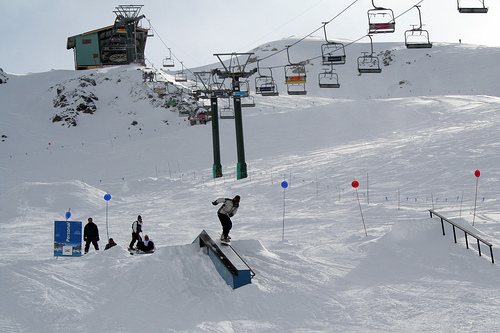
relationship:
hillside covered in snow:
[2, 32, 495, 329] [0, 34, 499, 331]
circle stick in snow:
[350, 181, 369, 238] [0, 34, 499, 331]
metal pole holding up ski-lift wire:
[228, 94, 249, 181] [252, 2, 359, 64]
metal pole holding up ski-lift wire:
[207, 97, 224, 179] [261, 2, 423, 73]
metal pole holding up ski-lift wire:
[207, 97, 224, 179] [140, 11, 195, 79]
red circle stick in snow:
[352, 180, 361, 189] [14, 48, 494, 319]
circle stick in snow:
[350, 181, 369, 238] [330, 212, 407, 269]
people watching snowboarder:
[52, 217, 145, 244] [214, 189, 246, 243]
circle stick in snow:
[465, 166, 483, 230] [14, 48, 494, 319]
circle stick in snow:
[350, 174, 374, 241] [14, 48, 494, 319]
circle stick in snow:
[277, 177, 291, 244] [14, 48, 494, 319]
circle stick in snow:
[98, 189, 116, 246] [14, 48, 494, 319]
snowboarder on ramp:
[159, 181, 310, 268] [195, 224, 253, 291]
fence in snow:
[426, 205, 496, 265] [290, 218, 412, 330]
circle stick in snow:
[350, 181, 369, 238] [14, 48, 494, 319]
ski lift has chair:
[126, 0, 497, 124] [402, 24, 440, 55]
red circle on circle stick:
[352, 180, 359, 189] [350, 181, 369, 238]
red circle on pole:
[473, 169, 480, 177] [472, 167, 480, 229]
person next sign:
[82, 217, 98, 252] [53, 220, 80, 257]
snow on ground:
[0, 34, 499, 331] [6, 43, 498, 332]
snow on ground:
[16, 262, 279, 331] [337, 255, 435, 326]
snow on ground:
[297, 124, 356, 155] [239, 96, 475, 328]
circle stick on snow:
[279, 179, 291, 243] [14, 48, 494, 319]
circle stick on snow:
[103, 193, 116, 246] [14, 48, 494, 319]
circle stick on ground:
[350, 181, 369, 238] [293, 213, 443, 274]